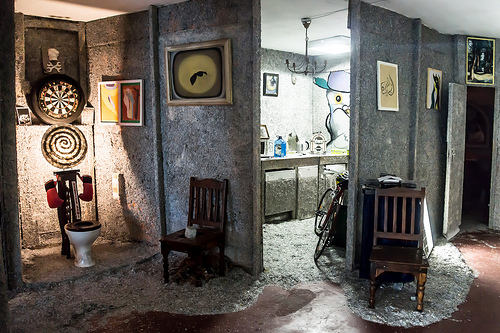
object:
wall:
[86, 0, 258, 276]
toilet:
[63, 218, 104, 267]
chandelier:
[281, 17, 339, 76]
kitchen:
[260, 0, 360, 265]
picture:
[426, 68, 449, 111]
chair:
[160, 177, 226, 286]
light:
[307, 36, 349, 54]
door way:
[259, 0, 352, 271]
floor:
[0, 214, 500, 332]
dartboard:
[30, 75, 86, 125]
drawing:
[311, 67, 351, 157]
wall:
[260, 46, 315, 140]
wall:
[359, 0, 458, 272]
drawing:
[375, 60, 400, 112]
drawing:
[262, 72, 279, 97]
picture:
[0, 0, 499, 332]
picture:
[463, 36, 497, 85]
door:
[442, 82, 468, 237]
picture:
[164, 40, 233, 105]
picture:
[116, 78, 143, 129]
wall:
[14, 11, 98, 249]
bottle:
[270, 133, 287, 156]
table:
[260, 150, 347, 227]